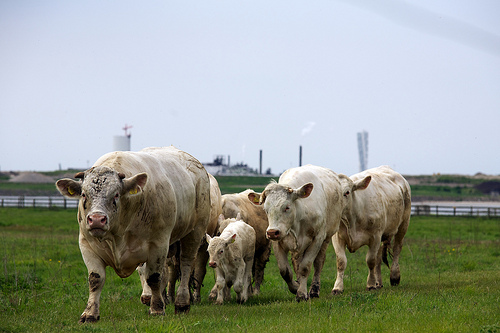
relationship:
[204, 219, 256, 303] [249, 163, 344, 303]
cow behind cow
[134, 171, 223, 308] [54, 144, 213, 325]
cow behind cow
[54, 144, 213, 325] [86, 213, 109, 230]
cow has nose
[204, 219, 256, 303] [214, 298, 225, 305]
cow has foot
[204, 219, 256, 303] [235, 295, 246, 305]
cow has foot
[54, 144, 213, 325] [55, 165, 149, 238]
cow has head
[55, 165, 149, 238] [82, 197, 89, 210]
head has spot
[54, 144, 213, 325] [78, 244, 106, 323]
cow has leg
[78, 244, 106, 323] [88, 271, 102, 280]
leg has spot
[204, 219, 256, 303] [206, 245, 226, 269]
cow has face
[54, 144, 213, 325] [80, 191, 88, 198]
cow has eye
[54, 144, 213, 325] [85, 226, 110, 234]
cow has mouth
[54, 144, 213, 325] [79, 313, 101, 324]
cow has hoof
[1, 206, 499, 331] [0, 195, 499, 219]
field has fence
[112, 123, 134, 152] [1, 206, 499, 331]
silo behind field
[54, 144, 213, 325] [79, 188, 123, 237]
cow has face